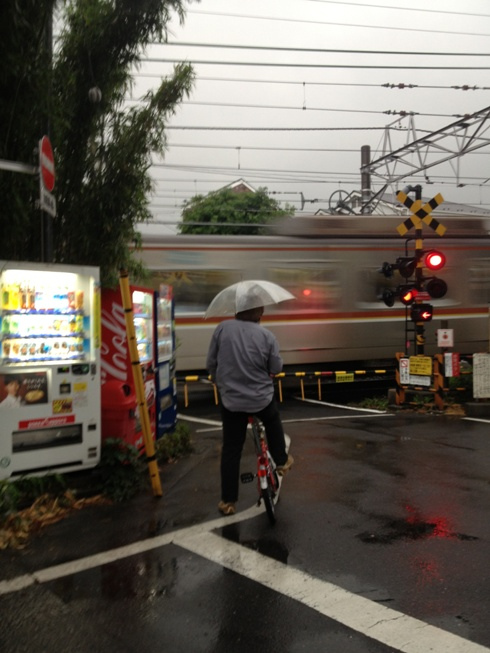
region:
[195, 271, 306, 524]
the person on a bike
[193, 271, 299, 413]
man holding an umbrella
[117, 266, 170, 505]
pole is color yellow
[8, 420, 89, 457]
opening of a machine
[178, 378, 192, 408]
the pole is yellow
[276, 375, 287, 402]
the pole is yellow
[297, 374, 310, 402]
the pole is yellow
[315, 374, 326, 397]
the pole is yellow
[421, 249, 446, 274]
the light is lit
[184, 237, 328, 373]
White umbrella with the man.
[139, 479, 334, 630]
White line on the road.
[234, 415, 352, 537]
Bike on the road.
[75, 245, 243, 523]
Coke machine on the road.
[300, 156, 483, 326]
Light by the tracks.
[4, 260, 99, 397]
Food in the vending machine.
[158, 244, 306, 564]
Man with an umbrella.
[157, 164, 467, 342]
Tree in the background.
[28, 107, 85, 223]
Red sign on the pole.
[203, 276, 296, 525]
Man on a bicycle holding an umbrella over his head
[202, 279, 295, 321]
Small umbrella over the person's head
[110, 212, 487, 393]
Train speeding by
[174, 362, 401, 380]
Gate down at the railroad crossing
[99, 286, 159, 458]
Coca Cola machine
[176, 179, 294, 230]
Tree on the other side of the tracks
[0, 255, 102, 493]
Vending machine on the side of the road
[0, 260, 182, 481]
Three vending machines near the side of the road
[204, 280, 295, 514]
Man holding an umbrella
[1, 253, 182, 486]
the vending machines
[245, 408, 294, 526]
a bicycle on the road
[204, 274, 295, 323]
a clear umbrella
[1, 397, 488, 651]
the white lines on the street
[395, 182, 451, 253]
the black and yellow sign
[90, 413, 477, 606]
the wet spots on the ground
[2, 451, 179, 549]
the leaves on the side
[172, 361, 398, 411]
the entrance to the parking lot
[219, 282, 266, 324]
the head of a man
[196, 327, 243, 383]
the arm of a man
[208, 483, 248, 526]
the foot of a man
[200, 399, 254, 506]
the leg of a man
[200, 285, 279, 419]
the back of a man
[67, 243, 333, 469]
a man near a coke machine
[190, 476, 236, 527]
a man wearing shoes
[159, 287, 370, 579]
a man on a bike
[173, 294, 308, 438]
a man wearing a shirt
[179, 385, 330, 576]
a man wearing jeans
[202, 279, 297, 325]
a small white umbrella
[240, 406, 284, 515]
the back of a red and black bike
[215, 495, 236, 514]
a man's brown tennis shoe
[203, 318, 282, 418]
a man's gray shirt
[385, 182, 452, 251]
a yellow and black railroad sign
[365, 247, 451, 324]
a railroad traffic light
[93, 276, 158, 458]
a red and white coke machine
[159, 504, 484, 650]
a white painted street marking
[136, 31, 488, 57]
a long electrical power line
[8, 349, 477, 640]
the ground is wet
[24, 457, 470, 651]
lines on the ground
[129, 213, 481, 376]
a speeding gray train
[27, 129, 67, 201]
a red and white sign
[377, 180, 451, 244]
a yellow and black sign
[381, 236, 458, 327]
a train signal light